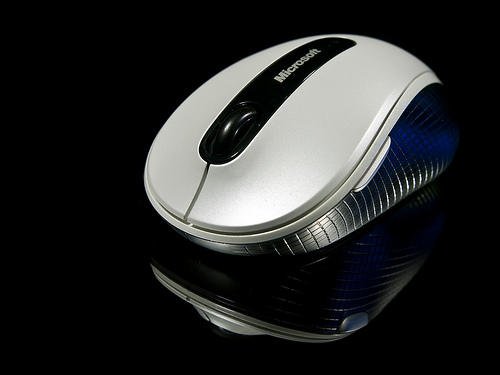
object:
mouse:
[144, 33, 455, 257]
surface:
[5, 184, 500, 341]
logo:
[274, 49, 322, 83]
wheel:
[204, 102, 258, 158]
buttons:
[353, 136, 392, 192]